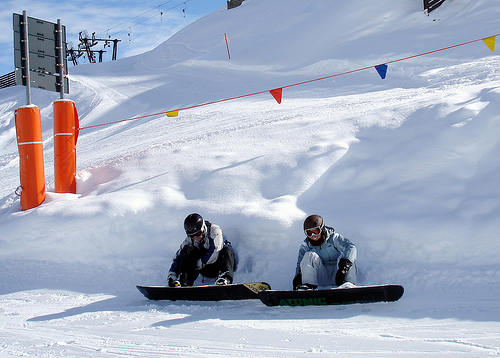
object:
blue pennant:
[374, 64, 388, 79]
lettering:
[280, 298, 327, 306]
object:
[14, 103, 46, 211]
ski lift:
[66, 30, 120, 68]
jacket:
[294, 225, 357, 278]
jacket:
[168, 220, 239, 272]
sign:
[12, 12, 69, 95]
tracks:
[0, 327, 309, 358]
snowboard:
[258, 284, 404, 306]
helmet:
[303, 214, 323, 229]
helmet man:
[166, 212, 239, 286]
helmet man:
[293, 214, 357, 290]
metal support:
[79, 32, 122, 42]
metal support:
[68, 49, 106, 52]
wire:
[104, 0, 185, 39]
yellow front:
[243, 283, 271, 294]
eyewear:
[304, 226, 321, 238]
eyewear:
[188, 230, 202, 238]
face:
[306, 228, 321, 241]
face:
[191, 231, 202, 241]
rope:
[73, 33, 500, 129]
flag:
[166, 110, 178, 117]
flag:
[269, 88, 283, 104]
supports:
[13, 99, 80, 209]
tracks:
[102, 84, 129, 99]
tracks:
[168, 42, 207, 53]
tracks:
[376, 333, 500, 351]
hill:
[0, 0, 500, 213]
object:
[52, 98, 80, 194]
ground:
[0, 63, 497, 358]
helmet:
[183, 212, 204, 234]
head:
[303, 214, 324, 241]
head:
[184, 213, 205, 242]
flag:
[483, 36, 496, 52]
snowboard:
[136, 282, 272, 302]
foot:
[296, 285, 314, 291]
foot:
[214, 277, 227, 285]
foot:
[168, 277, 182, 288]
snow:
[2, 1, 498, 354]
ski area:
[0, 0, 500, 358]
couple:
[166, 212, 359, 292]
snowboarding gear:
[257, 214, 404, 306]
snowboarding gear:
[134, 213, 271, 301]